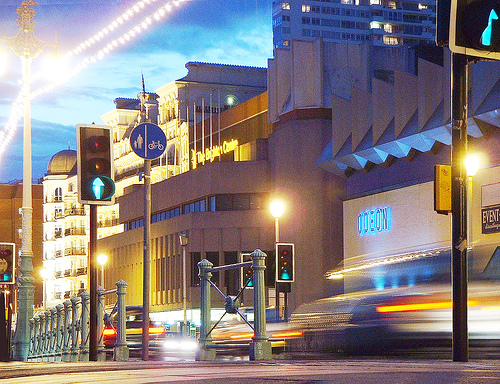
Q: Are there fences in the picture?
A: Yes, there is a fence.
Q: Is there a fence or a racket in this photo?
A: Yes, there is a fence.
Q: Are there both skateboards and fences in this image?
A: No, there is a fence but no skateboards.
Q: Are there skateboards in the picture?
A: No, there are no skateboards.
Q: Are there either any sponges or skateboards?
A: No, there are no skateboards or sponges.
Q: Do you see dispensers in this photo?
A: No, there are no dispensers.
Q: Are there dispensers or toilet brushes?
A: No, there are no dispensers or toilet brushes.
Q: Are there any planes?
A: No, there are no planes.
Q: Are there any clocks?
A: No, there are no clocks.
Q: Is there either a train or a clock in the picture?
A: No, there are no clocks or trains.